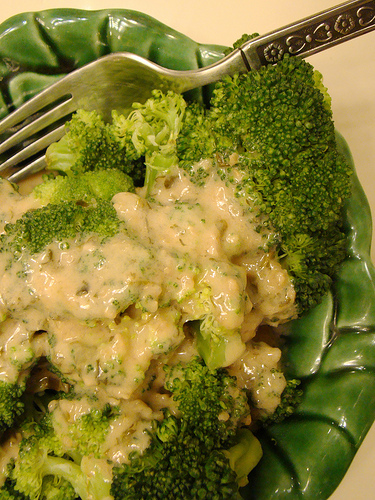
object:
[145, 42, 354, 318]
broccoli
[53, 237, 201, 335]
cheese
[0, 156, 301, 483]
cheese sauce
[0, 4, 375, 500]
bowl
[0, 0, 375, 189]
fork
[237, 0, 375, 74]
handle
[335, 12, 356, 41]
design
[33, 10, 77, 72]
cracks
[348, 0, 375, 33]
end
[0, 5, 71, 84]
groove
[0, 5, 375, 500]
plate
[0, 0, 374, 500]
background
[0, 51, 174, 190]
tines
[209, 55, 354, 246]
floret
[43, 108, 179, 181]
vegetable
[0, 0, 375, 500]
tabletop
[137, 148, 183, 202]
stem